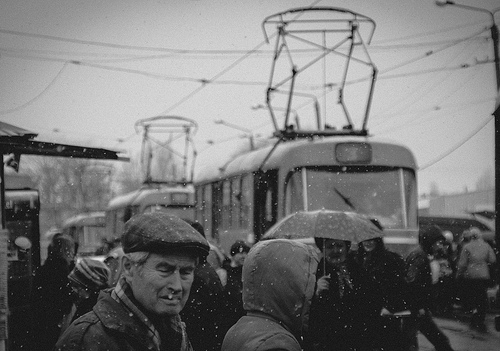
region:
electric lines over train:
[242, 6, 395, 138]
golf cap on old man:
[123, 210, 223, 263]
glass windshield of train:
[296, 176, 415, 226]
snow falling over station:
[10, 8, 475, 344]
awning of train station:
[0, 119, 127, 176]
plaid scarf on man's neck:
[109, 280, 181, 348]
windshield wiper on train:
[325, 181, 370, 218]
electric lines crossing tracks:
[18, 23, 434, 106]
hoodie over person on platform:
[240, 245, 330, 316]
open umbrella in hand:
[260, 201, 390, 278]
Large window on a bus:
[278, 163, 425, 244]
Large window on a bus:
[249, 170, 279, 225]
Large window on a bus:
[236, 174, 247, 226]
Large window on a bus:
[224, 176, 247, 226]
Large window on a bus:
[215, 179, 230, 234]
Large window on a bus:
[200, 181, 219, 247]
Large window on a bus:
[187, 181, 202, 223]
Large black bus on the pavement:
[183, 143, 435, 288]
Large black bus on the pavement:
[55, 193, 106, 251]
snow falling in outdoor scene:
[11, 52, 498, 339]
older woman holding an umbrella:
[276, 195, 431, 338]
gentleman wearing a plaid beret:
[88, 189, 230, 349]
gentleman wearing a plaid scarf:
[96, 271, 217, 347]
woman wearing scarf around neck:
[314, 233, 386, 316]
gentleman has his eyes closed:
[106, 203, 213, 321]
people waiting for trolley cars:
[18, 174, 495, 346]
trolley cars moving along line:
[170, 127, 458, 321]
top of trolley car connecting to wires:
[244, 23, 401, 137]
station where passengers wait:
[9, 119, 111, 344]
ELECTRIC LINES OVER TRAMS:
[234, 15, 498, 102]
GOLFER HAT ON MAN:
[110, 205, 215, 245]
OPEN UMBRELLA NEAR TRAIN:
[267, 207, 390, 239]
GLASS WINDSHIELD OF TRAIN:
[290, 165, 422, 239]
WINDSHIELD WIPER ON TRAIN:
[330, 182, 366, 221]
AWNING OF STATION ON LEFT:
[0, 132, 143, 172]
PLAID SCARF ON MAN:
[87, 292, 185, 349]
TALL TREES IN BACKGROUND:
[37, 144, 130, 209]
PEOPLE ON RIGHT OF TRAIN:
[436, 224, 498, 321]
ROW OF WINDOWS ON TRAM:
[185, 180, 254, 231]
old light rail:
[230, 119, 415, 203]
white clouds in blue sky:
[128, 13, 198, 51]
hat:
[122, 195, 212, 260]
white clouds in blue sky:
[405, 28, 455, 53]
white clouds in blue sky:
[405, 108, 445, 145]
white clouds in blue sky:
[418, 46, 463, 87]